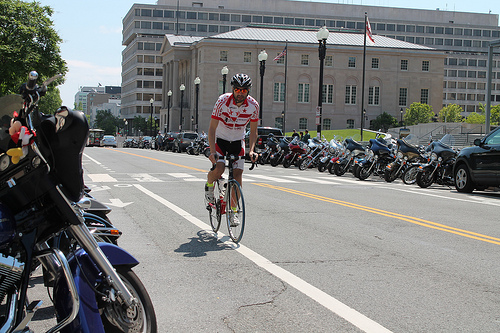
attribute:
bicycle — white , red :
[205, 152, 257, 243]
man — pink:
[203, 71, 261, 243]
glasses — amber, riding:
[234, 84, 249, 94]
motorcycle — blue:
[14, 142, 161, 327]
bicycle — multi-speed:
[203, 144, 249, 242]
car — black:
[446, 126, 498, 205]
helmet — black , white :
[231, 73, 251, 88]